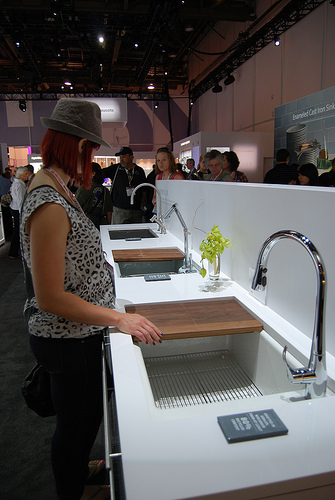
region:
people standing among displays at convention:
[21, 74, 308, 464]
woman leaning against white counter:
[11, 90, 164, 381]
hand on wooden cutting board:
[118, 289, 270, 356]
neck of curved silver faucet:
[241, 222, 325, 393]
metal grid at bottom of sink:
[138, 346, 264, 413]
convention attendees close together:
[3, 135, 251, 223]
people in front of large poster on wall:
[258, 77, 330, 188]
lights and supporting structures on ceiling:
[18, 7, 293, 98]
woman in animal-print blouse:
[14, 163, 133, 346]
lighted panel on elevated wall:
[24, 92, 181, 155]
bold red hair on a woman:
[43, 126, 96, 188]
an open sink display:
[130, 298, 299, 402]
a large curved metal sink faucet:
[250, 232, 331, 402]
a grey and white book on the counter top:
[214, 409, 292, 444]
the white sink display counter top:
[135, 421, 202, 481]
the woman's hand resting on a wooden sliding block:
[124, 298, 263, 352]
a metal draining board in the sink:
[152, 359, 259, 402]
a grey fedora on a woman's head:
[43, 94, 111, 151]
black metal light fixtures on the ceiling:
[24, 11, 189, 86]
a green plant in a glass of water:
[197, 232, 230, 294]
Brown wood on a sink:
[117, 290, 284, 345]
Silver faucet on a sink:
[239, 217, 334, 380]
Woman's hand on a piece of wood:
[100, 306, 167, 343]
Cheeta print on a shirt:
[16, 185, 139, 341]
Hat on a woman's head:
[29, 94, 124, 189]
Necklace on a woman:
[36, 155, 118, 248]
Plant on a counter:
[195, 215, 237, 316]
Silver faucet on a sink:
[151, 199, 202, 279]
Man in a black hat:
[103, 139, 155, 228]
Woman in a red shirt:
[146, 143, 192, 214]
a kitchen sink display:
[94, 171, 333, 491]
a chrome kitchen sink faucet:
[236, 225, 328, 405]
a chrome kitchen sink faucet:
[150, 197, 194, 275]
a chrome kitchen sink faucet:
[125, 179, 165, 232]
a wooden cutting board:
[115, 291, 263, 345]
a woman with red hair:
[14, 94, 166, 494]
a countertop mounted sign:
[213, 403, 288, 447]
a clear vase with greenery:
[186, 194, 235, 292]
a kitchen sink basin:
[123, 294, 324, 414]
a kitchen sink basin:
[104, 224, 158, 239]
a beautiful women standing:
[32, 104, 129, 394]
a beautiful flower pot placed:
[190, 220, 225, 299]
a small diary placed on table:
[205, 408, 296, 452]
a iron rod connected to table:
[98, 347, 128, 497]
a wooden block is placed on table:
[141, 299, 257, 343]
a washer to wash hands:
[255, 219, 327, 372]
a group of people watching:
[47, 148, 309, 189]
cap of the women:
[44, 94, 111, 149]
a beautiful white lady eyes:
[154, 156, 170, 162]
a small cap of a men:
[110, 142, 142, 157]